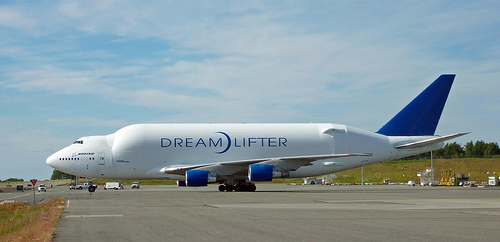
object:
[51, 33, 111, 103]
white clouds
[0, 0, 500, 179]
blue sky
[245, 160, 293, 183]
engines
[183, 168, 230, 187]
engines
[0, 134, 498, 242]
ground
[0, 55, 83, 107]
cloud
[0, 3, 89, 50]
cloud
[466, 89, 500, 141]
cloud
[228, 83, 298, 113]
clouds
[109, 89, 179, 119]
clouds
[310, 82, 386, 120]
clouds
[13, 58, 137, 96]
cloud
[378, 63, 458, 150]
tail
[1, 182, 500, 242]
runway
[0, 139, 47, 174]
clouds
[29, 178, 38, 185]
sign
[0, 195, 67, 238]
grass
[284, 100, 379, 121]
white clouds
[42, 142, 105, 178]
nose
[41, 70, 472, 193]
airplane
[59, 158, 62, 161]
window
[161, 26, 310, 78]
cloud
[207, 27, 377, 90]
white clouds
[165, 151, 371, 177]
wing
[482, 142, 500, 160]
trees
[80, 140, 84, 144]
window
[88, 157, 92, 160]
window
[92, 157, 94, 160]
window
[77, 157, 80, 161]
window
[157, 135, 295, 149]
name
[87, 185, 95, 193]
wheel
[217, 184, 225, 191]
wheel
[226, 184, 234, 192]
wheel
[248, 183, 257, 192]
wheel